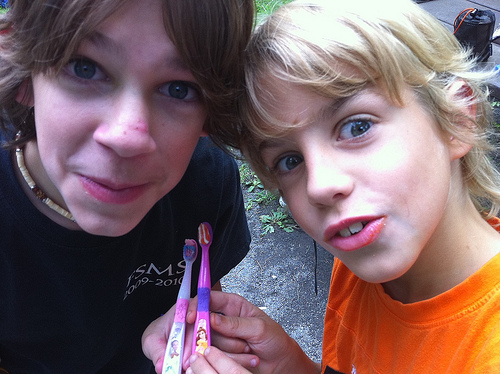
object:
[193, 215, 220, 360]
toothbrush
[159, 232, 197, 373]
toothbrush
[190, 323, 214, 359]
disney princess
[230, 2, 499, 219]
blonde hair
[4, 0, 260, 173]
brown hair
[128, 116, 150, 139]
pimple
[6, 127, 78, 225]
necklace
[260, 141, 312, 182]
green eyes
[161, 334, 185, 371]
frog princess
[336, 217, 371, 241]
front teeth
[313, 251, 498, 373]
orange shirt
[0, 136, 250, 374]
shirt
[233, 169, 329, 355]
pavement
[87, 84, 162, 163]
nose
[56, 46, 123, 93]
blue eyes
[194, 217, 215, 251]
bristles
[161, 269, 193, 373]
handle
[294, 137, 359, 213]
nose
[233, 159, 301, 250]
plants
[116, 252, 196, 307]
white writing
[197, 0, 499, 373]
boy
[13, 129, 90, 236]
neck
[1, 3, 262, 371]
boy